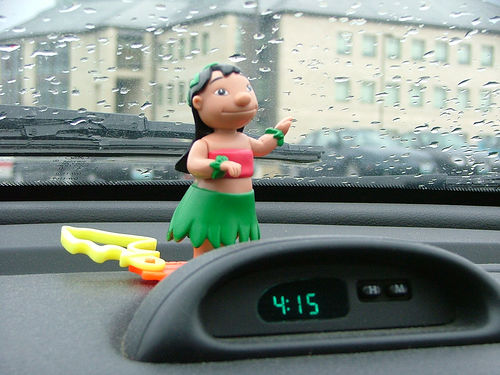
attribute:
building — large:
[5, 2, 499, 128]